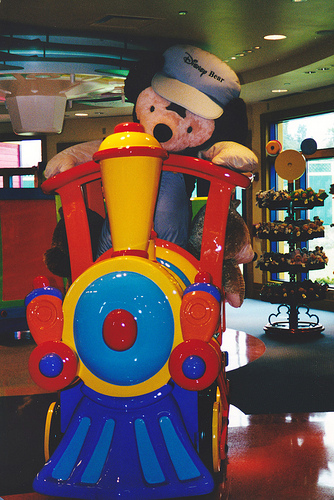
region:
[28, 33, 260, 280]
large stuffed disney bear toy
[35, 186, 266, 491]
disney plastic train toy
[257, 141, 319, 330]
rack of stuffed disney toys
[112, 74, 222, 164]
mickey mouse head as bears face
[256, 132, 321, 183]
mickey mouse ear topper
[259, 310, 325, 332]
mickey mouse head shape logos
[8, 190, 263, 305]
stuffed bear passangers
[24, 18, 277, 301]
three stuffed bears in toy train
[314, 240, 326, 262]
stuffed mickey mouse toy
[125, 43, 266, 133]
conducters hat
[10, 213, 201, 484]
this is a train toy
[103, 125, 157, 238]
this is a chimney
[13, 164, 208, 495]
the train is plastic like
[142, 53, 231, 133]
this is a doll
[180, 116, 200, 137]
this is a teddy bear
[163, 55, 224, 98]
it is wearing a cap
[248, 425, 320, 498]
this is a floor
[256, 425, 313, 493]
the floor is wooden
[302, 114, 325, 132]
this is a window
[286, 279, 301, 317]
this is a stand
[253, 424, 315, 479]
the floor is shiney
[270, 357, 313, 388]
the rug is black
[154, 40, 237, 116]
the hat is blue and tan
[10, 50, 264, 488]
two bears are in a train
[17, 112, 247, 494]
the train is red yellow and blue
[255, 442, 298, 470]
the floor is brown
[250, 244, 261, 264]
the bear has a nose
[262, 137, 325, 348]
the rack has stuffed animals on it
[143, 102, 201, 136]
the bear has eyes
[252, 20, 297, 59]
the light is on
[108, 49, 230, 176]
bear sitting in train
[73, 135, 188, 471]
train engine is blue, red and yellow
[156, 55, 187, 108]
teddy bear is wearing a hat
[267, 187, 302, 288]
stuffed animals on tiers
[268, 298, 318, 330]
bottom rack is shaped like mickey mouse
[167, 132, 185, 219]
bear is wearing coveralls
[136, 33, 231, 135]
bear is wearing a hat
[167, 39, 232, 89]
Disney Bear is written on the hat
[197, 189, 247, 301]
teddy bear looking out the window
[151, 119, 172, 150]
bear has black nose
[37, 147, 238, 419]
large toy riding train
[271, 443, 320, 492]
shiny red tiled floor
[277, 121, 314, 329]
tall metal structure with tiers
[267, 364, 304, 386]
black carpet near tile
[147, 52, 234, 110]
gray and black disney hat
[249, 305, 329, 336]
metal shaped mickey mouse ears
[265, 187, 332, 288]
three tiers of flowers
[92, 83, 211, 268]
large mickey mouse stuffed animal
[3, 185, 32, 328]
front desk of disney store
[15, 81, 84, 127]
center chandalier in building